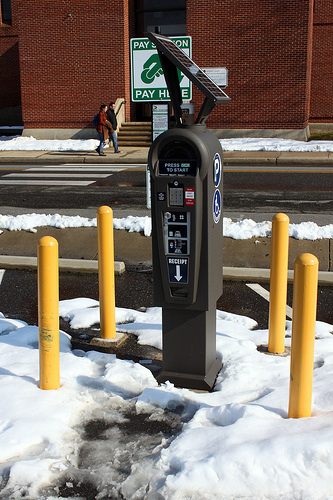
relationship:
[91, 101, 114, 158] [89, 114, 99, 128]
woman carrying backpack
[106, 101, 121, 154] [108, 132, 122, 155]
man wearing jeans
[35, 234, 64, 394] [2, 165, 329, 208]
pole near street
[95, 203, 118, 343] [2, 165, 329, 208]
pole near street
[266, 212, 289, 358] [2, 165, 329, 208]
pole near street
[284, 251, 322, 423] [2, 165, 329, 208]
pole near street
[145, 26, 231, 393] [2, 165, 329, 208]
parking meter near street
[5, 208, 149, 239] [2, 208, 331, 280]
snow on sidewalk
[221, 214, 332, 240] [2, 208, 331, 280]
snow on sidewalk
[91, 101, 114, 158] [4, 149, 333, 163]
woman on sidewalk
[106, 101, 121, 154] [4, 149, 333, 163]
man on sidewalk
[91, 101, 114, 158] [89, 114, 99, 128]
woman has backpack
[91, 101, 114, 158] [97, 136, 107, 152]
woman wearing jeans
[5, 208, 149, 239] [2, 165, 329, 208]
snow near street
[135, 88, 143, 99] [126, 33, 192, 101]
letter on sign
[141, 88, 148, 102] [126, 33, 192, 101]
letter on sign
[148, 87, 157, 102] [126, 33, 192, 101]
letter on sign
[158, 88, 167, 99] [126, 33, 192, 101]
letter on sign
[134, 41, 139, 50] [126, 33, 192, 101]
letter on sign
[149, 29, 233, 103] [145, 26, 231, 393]
solar panel on parking meter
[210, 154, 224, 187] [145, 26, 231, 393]
sign on parking meter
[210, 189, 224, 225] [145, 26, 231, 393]
sign on parking meter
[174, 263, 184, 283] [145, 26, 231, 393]
arrow on parking meter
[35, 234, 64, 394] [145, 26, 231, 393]
pole near parking meter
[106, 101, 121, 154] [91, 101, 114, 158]
man with woman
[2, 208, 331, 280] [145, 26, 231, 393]
sidewalk behind parking meter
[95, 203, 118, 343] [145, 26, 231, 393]
pole near parking meter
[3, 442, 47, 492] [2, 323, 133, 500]
footprint in snow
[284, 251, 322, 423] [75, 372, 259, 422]
pole making shadow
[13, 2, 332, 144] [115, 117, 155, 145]
building has stairs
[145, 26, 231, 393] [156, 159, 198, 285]
parking meter has instructions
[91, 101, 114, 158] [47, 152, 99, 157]
woman has shadow